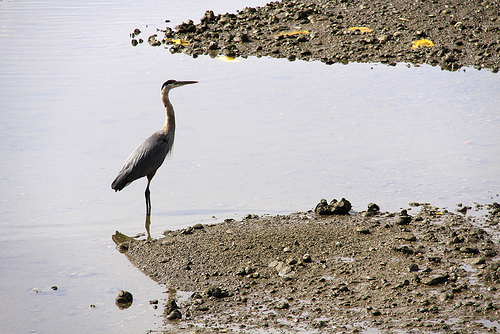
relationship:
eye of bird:
[166, 80, 176, 89] [109, 79, 199, 237]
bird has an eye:
[109, 79, 199, 237] [166, 80, 176, 89]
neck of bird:
[162, 98, 178, 132] [109, 79, 199, 237]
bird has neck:
[109, 79, 199, 237] [162, 98, 178, 132]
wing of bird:
[130, 139, 166, 175] [109, 79, 199, 237]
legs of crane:
[144, 175, 158, 248] [87, 76, 208, 247]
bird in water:
[109, 79, 199, 237] [12, 22, 495, 322]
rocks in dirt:
[193, 22, 237, 48] [147, 0, 497, 81]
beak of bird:
[172, 80, 199, 87] [106, 71, 206, 241]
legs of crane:
[144, 175, 152, 239] [108, 73, 207, 262]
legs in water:
[144, 175, 152, 239] [5, 54, 484, 234]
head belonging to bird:
[159, 78, 199, 92] [109, 79, 199, 237]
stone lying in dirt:
[277, 265, 293, 278] [113, 196, 483, 331]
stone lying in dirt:
[282, 244, 291, 254] [113, 196, 483, 331]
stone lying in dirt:
[300, 251, 310, 261] [113, 196, 483, 331]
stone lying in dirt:
[366, 244, 376, 253] [113, 196, 483, 331]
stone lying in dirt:
[406, 261, 421, 271] [113, 196, 483, 331]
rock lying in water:
[113, 288, 133, 307] [1, 1, 484, 331]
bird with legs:
[109, 79, 199, 237] [123, 167, 172, 257]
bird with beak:
[93, 63, 187, 253] [174, 69, 201, 98]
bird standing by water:
[109, 79, 199, 237] [261, 112, 483, 201]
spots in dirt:
[169, 30, 440, 60] [206, 0, 486, 60]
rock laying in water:
[116, 278, 140, 311] [19, 189, 99, 297]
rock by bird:
[116, 278, 140, 311] [105, 62, 216, 252]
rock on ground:
[393, 25, 406, 35] [339, 5, 475, 62]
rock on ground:
[300, 251, 312, 267] [239, 219, 402, 330]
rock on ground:
[283, 253, 301, 264] [215, 229, 448, 316]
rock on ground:
[240, 256, 250, 275] [258, 226, 450, 326]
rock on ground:
[403, 257, 423, 275] [300, 227, 341, 327]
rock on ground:
[427, 248, 446, 273] [314, 232, 497, 321]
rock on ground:
[422, 240, 432, 254] [258, 226, 450, 326]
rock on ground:
[400, 220, 412, 237] [311, 230, 472, 319]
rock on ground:
[388, 208, 415, 228] [285, 208, 466, 292]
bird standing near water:
[109, 79, 199, 237] [202, 73, 405, 196]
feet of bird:
[136, 229, 164, 247] [109, 79, 199, 237]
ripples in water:
[0, 23, 122, 108] [2, 1, 435, 331]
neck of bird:
[162, 90, 176, 130] [106, 75, 198, 243]